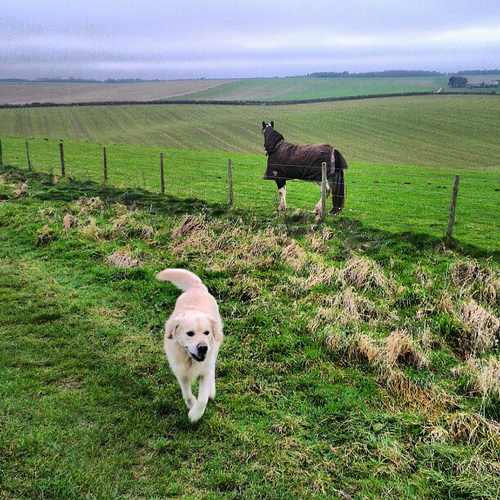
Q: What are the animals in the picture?
A: A dog and horse.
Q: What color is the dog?
A: Tan.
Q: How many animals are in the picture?
A: Two.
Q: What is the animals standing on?
A: Grass.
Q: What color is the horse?
A: Brown.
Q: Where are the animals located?
A: On a farm.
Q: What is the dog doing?
A: Walking.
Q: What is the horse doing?
A: Standing there.